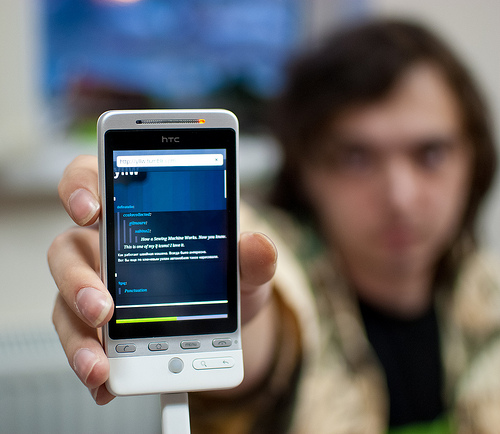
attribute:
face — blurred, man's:
[301, 60, 489, 270]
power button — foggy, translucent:
[169, 356, 184, 375]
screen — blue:
[109, 129, 233, 331]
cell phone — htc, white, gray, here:
[97, 104, 244, 399]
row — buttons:
[113, 339, 234, 352]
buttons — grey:
[114, 338, 235, 355]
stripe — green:
[390, 412, 447, 433]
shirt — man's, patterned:
[359, 299, 440, 422]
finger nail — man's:
[76, 283, 117, 329]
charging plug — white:
[158, 394, 193, 431]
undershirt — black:
[364, 304, 449, 407]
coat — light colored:
[160, 204, 499, 429]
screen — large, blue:
[36, 11, 313, 107]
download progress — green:
[115, 309, 227, 328]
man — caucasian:
[43, 13, 498, 433]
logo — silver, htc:
[159, 134, 180, 146]